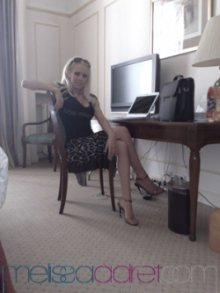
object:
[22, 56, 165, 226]
woman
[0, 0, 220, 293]
room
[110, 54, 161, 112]
tv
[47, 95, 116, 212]
chair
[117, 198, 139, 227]
shoe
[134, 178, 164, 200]
shoe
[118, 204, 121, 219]
high heel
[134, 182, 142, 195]
high heel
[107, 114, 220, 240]
table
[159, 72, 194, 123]
bag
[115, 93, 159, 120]
laptop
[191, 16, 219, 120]
lamp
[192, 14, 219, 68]
shade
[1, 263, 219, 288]
address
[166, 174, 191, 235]
trash can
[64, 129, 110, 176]
skirt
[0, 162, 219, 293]
carpet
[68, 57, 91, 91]
head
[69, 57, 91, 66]
sunglasses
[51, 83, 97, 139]
tank top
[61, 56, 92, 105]
hair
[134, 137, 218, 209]
wires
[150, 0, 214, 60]
picture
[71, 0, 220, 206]
wall